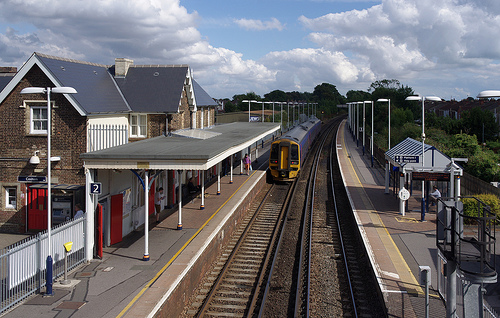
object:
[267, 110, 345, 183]
train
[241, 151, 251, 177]
person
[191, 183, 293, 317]
tracks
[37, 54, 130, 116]
roof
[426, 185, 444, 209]
person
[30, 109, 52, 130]
window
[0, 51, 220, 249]
building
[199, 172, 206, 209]
pole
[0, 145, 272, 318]
platform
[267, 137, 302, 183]
train front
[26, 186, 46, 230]
red door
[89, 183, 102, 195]
2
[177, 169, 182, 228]
white pole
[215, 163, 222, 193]
white pole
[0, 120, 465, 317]
ground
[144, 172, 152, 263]
pole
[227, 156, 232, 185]
pole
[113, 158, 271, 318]
line